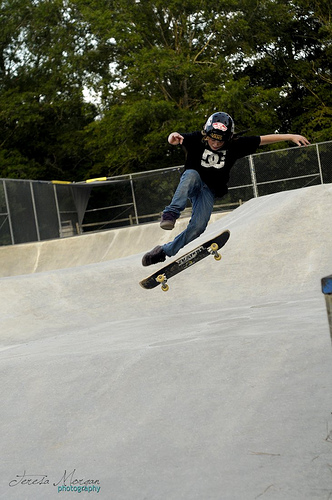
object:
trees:
[68, 1, 97, 182]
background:
[2, 3, 328, 356]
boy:
[141, 111, 310, 266]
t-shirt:
[179, 132, 261, 201]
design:
[199, 149, 227, 169]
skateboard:
[140, 229, 230, 292]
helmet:
[202, 110, 234, 141]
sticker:
[211, 122, 228, 131]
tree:
[54, 24, 180, 177]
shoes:
[141, 245, 171, 268]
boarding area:
[1, 183, 331, 499]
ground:
[0, 179, 331, 498]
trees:
[0, 2, 30, 210]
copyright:
[11, 465, 101, 499]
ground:
[184, 44, 248, 75]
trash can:
[58, 216, 73, 238]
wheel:
[210, 240, 219, 252]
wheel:
[213, 253, 221, 260]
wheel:
[155, 275, 165, 282]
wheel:
[161, 283, 169, 291]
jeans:
[159, 167, 212, 257]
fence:
[0, 139, 331, 247]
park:
[0, 182, 331, 499]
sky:
[1, 3, 330, 135]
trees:
[258, 2, 330, 158]